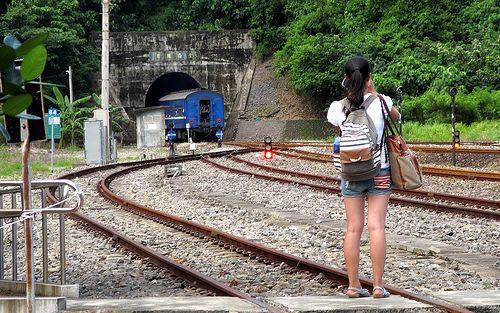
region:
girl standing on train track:
[321, 35, 418, 307]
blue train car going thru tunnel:
[117, 63, 239, 166]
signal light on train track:
[440, 70, 465, 183]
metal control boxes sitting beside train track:
[76, 91, 135, 168]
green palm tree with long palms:
[41, 65, 98, 161]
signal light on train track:
[260, 125, 290, 174]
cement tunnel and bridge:
[75, 7, 287, 141]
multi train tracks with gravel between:
[50, 146, 370, 298]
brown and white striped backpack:
[331, 86, 387, 190]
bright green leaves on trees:
[290, 0, 435, 71]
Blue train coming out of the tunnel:
[150, 80, 230, 135]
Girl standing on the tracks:
[330, 55, 405, 295]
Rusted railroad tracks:
[85, 180, 290, 310]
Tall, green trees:
[285, 0, 495, 61]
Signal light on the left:
[255, 130, 275, 155]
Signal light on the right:
[445, 125, 465, 155]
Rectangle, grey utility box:
[75, 110, 110, 161]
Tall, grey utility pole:
[90, 0, 115, 115]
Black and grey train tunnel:
[110, 26, 245, 86]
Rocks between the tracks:
[202, 185, 302, 218]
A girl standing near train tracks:
[326, 56, 424, 297]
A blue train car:
[158, 87, 225, 139]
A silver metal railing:
[0, 178, 84, 285]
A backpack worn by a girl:
[334, 94, 381, 181]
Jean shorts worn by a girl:
[341, 167, 394, 194]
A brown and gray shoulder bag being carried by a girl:
[378, 92, 423, 190]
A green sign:
[43, 105, 60, 139]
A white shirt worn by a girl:
[326, 92, 392, 167]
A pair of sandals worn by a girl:
[346, 284, 390, 297]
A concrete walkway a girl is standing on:
[1, 287, 499, 311]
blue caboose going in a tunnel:
[147, 59, 229, 146]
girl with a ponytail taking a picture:
[324, 41, 432, 304]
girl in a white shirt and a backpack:
[311, 39, 441, 299]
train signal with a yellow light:
[439, 59, 474, 174]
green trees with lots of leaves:
[268, 11, 475, 56]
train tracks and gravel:
[76, 161, 236, 276]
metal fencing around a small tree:
[9, 134, 84, 302]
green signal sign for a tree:
[41, 102, 65, 172]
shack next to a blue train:
[119, 93, 180, 165]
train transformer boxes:
[72, 97, 155, 183]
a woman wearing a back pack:
[295, 46, 422, 308]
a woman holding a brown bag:
[297, 41, 413, 255]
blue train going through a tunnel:
[96, 62, 235, 153]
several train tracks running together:
[49, 114, 473, 286]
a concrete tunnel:
[54, 13, 279, 133]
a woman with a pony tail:
[323, 52, 378, 107]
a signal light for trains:
[423, 63, 472, 177]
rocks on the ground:
[78, 170, 296, 283]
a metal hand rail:
[6, 155, 81, 312]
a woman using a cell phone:
[276, 43, 418, 293]